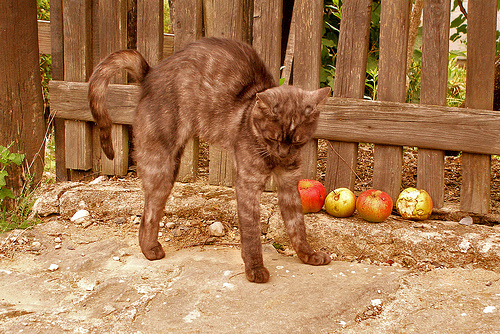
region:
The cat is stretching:
[73, 36, 326, 271]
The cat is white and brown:
[73, 35, 331, 276]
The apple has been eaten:
[401, 176, 439, 219]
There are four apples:
[289, 170, 436, 220]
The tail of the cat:
[71, 46, 146, 162]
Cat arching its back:
[86, 34, 333, 284]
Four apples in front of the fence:
[292, 176, 434, 223]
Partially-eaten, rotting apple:
[398, 183, 431, 219]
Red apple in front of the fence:
[354, 183, 391, 225]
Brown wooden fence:
[51, 0, 497, 213]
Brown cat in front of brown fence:
[88, 35, 330, 282]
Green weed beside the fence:
[0, 137, 22, 224]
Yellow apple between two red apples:
[326, 185, 353, 214]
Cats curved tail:
[85, 43, 147, 159]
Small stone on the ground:
[206, 218, 226, 239]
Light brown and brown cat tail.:
[86, 50, 148, 160]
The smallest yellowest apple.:
[321, 185, 353, 215]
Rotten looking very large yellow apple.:
[395, 182, 432, 217]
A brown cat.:
[86, 35, 332, 283]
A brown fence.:
[45, 2, 498, 222]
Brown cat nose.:
[276, 142, 286, 157]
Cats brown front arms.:
[228, 148, 329, 281]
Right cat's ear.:
[255, 89, 275, 113]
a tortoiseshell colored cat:
[90, 38, 332, 281]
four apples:
[296, 174, 433, 221]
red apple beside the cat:
[86, 38, 327, 283]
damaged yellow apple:
[398, 188, 433, 220]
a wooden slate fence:
[45, 0, 499, 214]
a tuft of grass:
[1, 143, 45, 228]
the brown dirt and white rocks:
[0, 181, 496, 331]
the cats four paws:
[95, 37, 330, 282]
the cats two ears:
[88, 37, 328, 282]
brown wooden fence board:
[460, 3, 498, 219]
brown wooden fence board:
[416, 4, 448, 212]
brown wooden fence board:
[373, 1, 405, 207]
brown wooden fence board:
[323, 0, 367, 203]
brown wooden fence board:
[293, 2, 317, 187]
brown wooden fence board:
[251, 5, 278, 85]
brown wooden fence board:
[204, 3, 240, 185]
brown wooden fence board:
[134, 1, 160, 78]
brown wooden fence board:
[96, 0, 131, 177]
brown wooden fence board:
[61, 0, 91, 172]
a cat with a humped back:
[90, 32, 331, 283]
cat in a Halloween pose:
[90, 36, 331, 283]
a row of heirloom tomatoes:
[293, 178, 433, 220]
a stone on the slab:
[71, 208, 88, 225]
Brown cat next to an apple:
[82, 36, 333, 288]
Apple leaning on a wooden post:
[396, 182, 435, 226]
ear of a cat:
[253, 85, 276, 114]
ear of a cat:
[302, 80, 332, 114]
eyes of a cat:
[265, 130, 305, 146]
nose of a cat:
[277, 144, 291, 158]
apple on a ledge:
[324, 184, 361, 217]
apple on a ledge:
[351, 187, 393, 222]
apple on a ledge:
[395, 185, 435, 221]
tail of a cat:
[85, 49, 140, 157]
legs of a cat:
[131, 140, 331, 280]